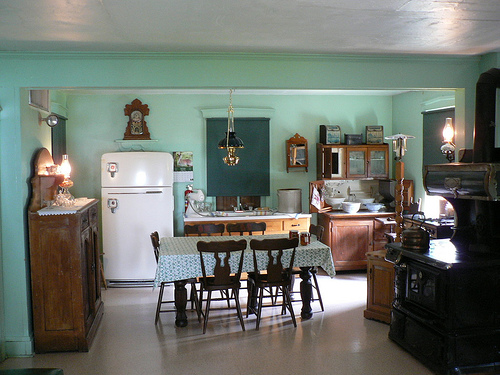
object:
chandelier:
[217, 106, 245, 167]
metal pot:
[277, 188, 303, 213]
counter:
[182, 207, 312, 222]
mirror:
[283, 127, 310, 172]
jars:
[300, 231, 309, 246]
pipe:
[457, 54, 497, 121]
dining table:
[152, 233, 337, 327]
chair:
[150, 231, 202, 326]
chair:
[183, 223, 232, 310]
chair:
[226, 221, 274, 306]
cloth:
[151, 232, 337, 293]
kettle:
[399, 211, 430, 249]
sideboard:
[280, 117, 410, 284]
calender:
[171, 151, 194, 182]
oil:
[58, 177, 75, 188]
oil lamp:
[58, 151, 75, 204]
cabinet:
[26, 198, 105, 355]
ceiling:
[1, 2, 499, 96]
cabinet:
[316, 143, 347, 180]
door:
[325, 149, 330, 177]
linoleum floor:
[1, 270, 438, 374]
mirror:
[284, 137, 309, 172]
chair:
[246, 237, 298, 331]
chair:
[196, 239, 247, 335]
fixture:
[227, 87, 235, 113]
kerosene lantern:
[401, 211, 430, 250]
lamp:
[440, 116, 456, 155]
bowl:
[340, 202, 361, 215]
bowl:
[363, 203, 384, 213]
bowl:
[324, 197, 347, 209]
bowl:
[355, 197, 375, 210]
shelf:
[320, 200, 407, 218]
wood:
[448, 280, 470, 297]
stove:
[396, 209, 456, 238]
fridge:
[97, 150, 173, 289]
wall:
[61, 91, 392, 237]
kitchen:
[0, 0, 500, 375]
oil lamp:
[440, 118, 455, 154]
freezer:
[99, 150, 173, 189]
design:
[155, 237, 331, 287]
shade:
[205, 116, 269, 196]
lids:
[289, 229, 300, 233]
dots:
[167, 240, 179, 248]